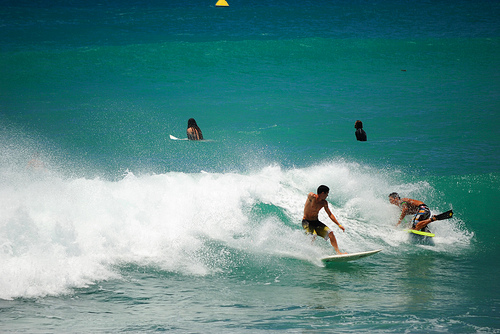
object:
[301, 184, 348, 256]
surfer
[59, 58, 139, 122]
ocean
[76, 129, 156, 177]
white and green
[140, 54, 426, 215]
scene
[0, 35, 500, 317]
photo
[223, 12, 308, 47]
blue portion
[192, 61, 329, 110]
water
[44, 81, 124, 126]
green portion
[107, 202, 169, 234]
white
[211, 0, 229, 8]
yellow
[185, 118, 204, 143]
person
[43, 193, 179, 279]
wave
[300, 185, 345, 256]
man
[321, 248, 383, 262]
surfboard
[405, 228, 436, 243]
green and yellow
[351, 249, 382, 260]
top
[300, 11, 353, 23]
dark line